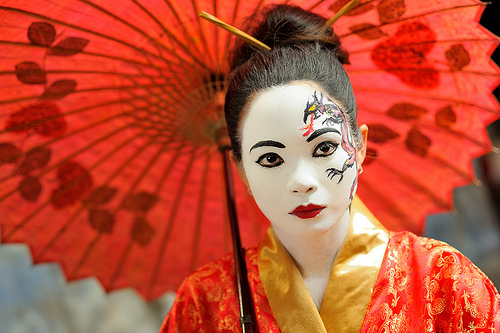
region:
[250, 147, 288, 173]
the woman's right eye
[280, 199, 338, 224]
the woman's bright red lips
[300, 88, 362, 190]
a dragon painted on the woman's face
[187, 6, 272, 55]
a brown stick in her hair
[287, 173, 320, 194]
the woman's nose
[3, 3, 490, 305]
a bright red umbrella being held by the woman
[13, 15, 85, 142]
the pattern of a flower and leaves on the umbrella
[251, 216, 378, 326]
the gold silk collar of the kimono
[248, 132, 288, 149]
the woman's right eyebrow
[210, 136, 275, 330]
the long black handle of the umbrella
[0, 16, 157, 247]
Leaf decorations on a red umbrella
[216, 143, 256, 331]
The black stick of the umbrella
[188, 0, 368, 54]
Woman with dark hair in a bun with brown stick hair decorations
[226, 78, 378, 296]
A woman's face and neck painted white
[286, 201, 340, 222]
The woman's lips painted red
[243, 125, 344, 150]
Black eyebrows painted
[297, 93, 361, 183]
An image painted on the left side of the woman's face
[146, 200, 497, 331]
The woman dressed in a red and gold outfit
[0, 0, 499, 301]
A large red decorated umbrella with pointy edges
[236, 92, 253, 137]
Edge of the woman's head that is not painted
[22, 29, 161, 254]
black printed leaves on umbrella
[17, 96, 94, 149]
black printed flower on umbrella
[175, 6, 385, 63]
brown chopsticks for hair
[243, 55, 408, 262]
white painted face for asian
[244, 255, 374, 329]
yellow gold collar of robe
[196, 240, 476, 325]
red and gold Chinese robe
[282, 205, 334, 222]
red womans lipstick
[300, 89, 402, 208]
painted dragon on womans face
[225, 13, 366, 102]
dark brown hair in a bun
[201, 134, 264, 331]
black handle to umbrella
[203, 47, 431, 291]
Woman is wearing white face makeup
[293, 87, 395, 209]
Woman has a dragon painted on her face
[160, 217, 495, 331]
Woman is wearing a red and gold outfit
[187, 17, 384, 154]
Woman has dark colored hair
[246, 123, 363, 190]
Woman has dark colored eyes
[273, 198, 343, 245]
Woman's lipstick is bright red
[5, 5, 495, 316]
Woman is holding a umbrella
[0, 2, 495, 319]
Umbrella is bright red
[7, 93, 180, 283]
Umbrella has dark red leaf designs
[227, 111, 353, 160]
Woman's eyebrows are painted black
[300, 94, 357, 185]
Painted dragon on the girl's face.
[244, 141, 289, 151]
The girl's left eyebrow.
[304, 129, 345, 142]
The girl's right eyebrow.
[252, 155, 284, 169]
The girl's left eye.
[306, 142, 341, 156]
The girl's right eye.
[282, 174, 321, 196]
The girl's tip of the nose and nostrils.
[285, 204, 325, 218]
The girl's painted red lips.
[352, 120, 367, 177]
The girl's right ear.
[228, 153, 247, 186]
The girl's left ear.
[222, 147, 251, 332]
The black pole of the red umbrella.